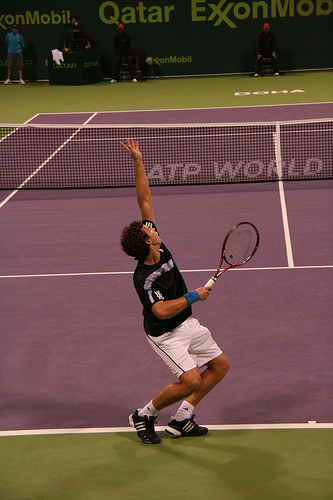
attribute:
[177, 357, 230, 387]
knees — bent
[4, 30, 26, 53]
shirt — blue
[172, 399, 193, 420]
sock — white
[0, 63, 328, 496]
floor — tennis court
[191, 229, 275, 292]
racket — red and black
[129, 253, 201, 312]
shirt — black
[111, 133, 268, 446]
tennis player — ball-serving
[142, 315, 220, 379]
shorts — white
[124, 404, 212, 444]
shoes — black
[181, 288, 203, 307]
sweatband — blue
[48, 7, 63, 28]
lettering — light green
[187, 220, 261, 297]
racket — tennis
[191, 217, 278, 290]
racket — red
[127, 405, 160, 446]
foot — man's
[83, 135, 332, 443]
player — ball-serving, tennis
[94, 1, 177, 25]
lettering — light green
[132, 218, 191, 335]
shirt — black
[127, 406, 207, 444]
tennis shoes — Adidas 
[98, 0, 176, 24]
lettering — light green